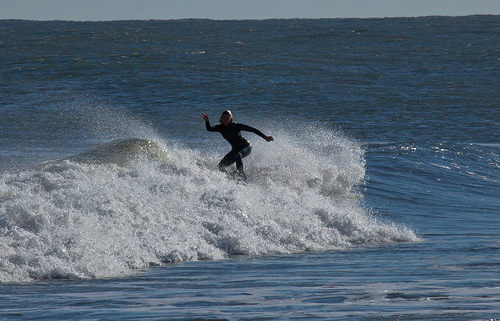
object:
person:
[200, 109, 274, 181]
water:
[0, 16, 500, 321]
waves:
[7, 119, 428, 283]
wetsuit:
[205, 120, 268, 180]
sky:
[1, 0, 500, 19]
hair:
[218, 109, 234, 123]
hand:
[200, 112, 209, 121]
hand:
[265, 135, 275, 142]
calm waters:
[0, 30, 500, 93]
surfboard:
[225, 176, 247, 185]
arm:
[237, 123, 267, 139]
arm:
[205, 121, 218, 132]